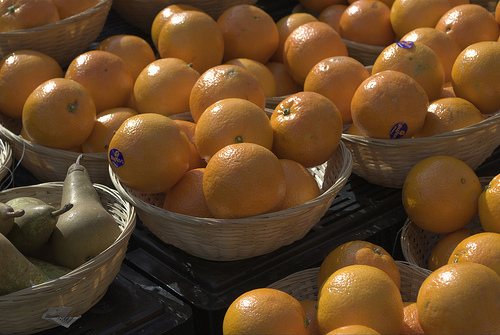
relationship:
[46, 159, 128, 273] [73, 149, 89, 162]
pear with stem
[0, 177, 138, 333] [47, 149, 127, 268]
bowl of pear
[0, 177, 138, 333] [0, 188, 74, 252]
bowl of pear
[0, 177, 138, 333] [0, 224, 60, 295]
bowl of pear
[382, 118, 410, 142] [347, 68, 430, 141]
sticker on orange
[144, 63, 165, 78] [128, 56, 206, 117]
sunlight on orange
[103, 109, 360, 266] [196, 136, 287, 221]
basket with orange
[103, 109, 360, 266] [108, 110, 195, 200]
basket with orange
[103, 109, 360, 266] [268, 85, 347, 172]
basket with orange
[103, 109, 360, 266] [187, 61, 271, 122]
basket with orange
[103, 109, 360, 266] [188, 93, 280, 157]
basket with orange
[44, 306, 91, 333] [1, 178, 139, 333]
label on basket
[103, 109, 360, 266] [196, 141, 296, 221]
basket has orange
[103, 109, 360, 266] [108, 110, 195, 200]
basket has orange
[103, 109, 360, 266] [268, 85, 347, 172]
basket has orange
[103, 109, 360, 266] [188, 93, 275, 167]
basket has orange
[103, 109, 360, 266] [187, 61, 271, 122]
basket has orange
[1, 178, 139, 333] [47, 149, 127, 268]
basket with pear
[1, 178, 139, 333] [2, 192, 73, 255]
basket with pear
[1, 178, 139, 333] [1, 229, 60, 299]
basket with pear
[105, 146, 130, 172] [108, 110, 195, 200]
sticker on orange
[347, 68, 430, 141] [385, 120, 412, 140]
orange with sticker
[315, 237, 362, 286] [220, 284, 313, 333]
shadow cast on orange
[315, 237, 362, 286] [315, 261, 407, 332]
shadow cast on orange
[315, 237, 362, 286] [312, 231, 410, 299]
shadow cast on orange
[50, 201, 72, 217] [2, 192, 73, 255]
stem of pear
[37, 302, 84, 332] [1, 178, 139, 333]
paper on basket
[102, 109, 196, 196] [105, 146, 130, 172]
orange has sticker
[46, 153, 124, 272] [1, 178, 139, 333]
pear in basket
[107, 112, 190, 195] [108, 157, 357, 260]
orange in basket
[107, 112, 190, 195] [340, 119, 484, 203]
orange in basket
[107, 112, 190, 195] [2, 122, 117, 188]
orange in basket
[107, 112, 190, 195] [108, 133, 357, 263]
orange in basket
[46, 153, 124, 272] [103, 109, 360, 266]
pear sitting on basket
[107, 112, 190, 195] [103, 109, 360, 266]
orange sitting on basket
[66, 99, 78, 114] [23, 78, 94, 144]
stem of the orange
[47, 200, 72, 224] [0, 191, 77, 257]
stem on a pear